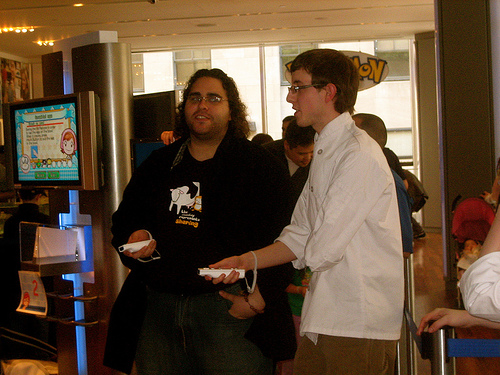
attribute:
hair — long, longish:
[169, 67, 250, 140]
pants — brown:
[295, 332, 401, 372]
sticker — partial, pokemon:
[282, 48, 389, 92]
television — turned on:
[5, 105, 102, 187]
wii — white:
[6, 204, 113, 292]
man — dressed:
[128, 63, 296, 295]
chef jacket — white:
[197, 48, 412, 373]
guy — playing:
[111, 67, 298, 372]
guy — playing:
[206, 48, 406, 372]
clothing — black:
[100, 122, 298, 369]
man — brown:
[100, 67, 300, 373]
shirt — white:
[274, 108, 404, 342]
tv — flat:
[8, 93, 103, 195]